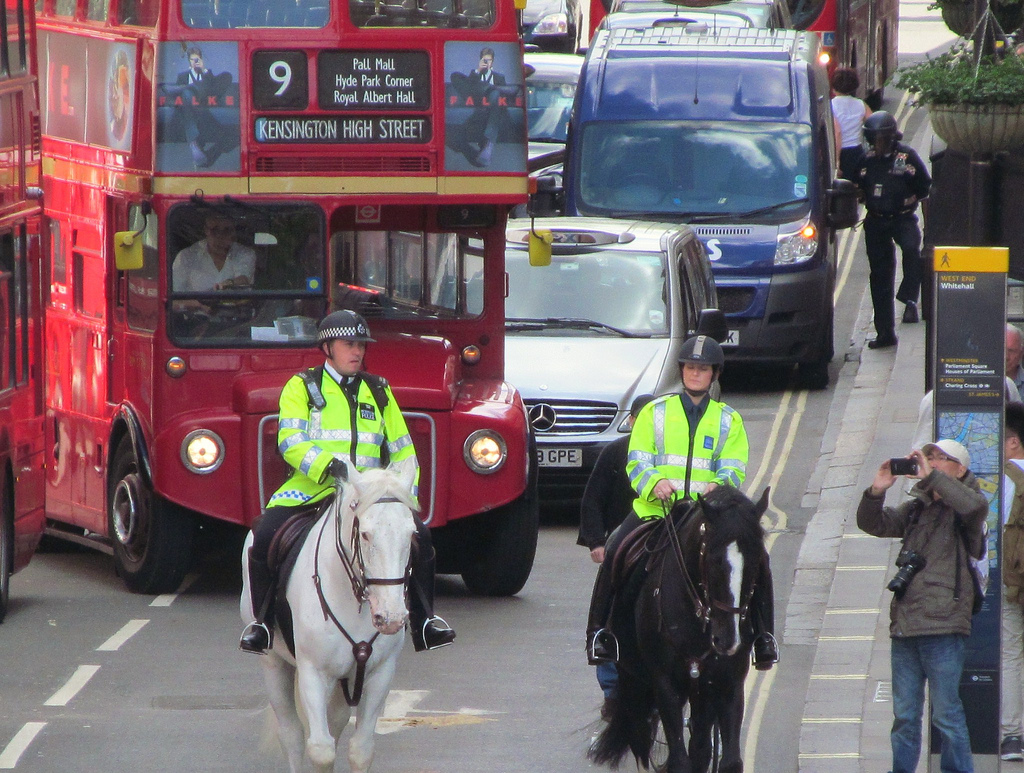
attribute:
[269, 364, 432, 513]
jacket — yellow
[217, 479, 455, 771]
horse — white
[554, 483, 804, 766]
horse — black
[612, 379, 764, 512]
jacket — yellow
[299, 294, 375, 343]
helmet — black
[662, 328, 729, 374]
helmet — black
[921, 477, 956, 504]
neck — man's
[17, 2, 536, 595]
bus — red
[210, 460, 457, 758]
horse — silver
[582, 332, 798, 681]
woman — police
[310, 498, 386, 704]
rein — horse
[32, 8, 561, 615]
decker bus — double, large, red